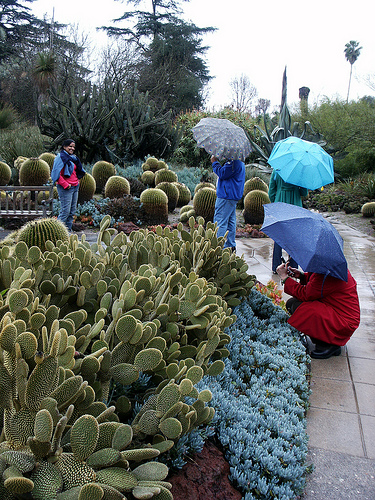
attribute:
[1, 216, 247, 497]
cacti — round, short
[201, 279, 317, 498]
succulents — green 